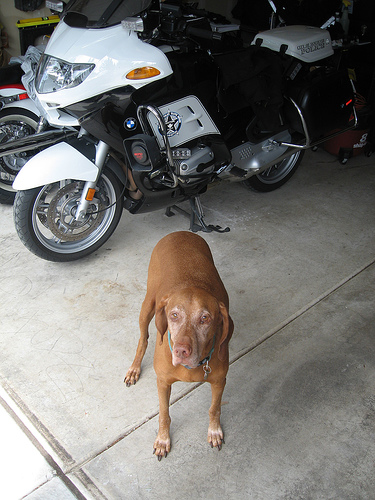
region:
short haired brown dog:
[118, 226, 273, 468]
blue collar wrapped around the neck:
[160, 330, 220, 377]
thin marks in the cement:
[30, 324, 104, 410]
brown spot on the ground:
[72, 271, 135, 322]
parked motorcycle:
[15, 12, 354, 263]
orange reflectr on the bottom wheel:
[84, 185, 98, 204]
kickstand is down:
[181, 193, 232, 233]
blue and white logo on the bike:
[121, 113, 139, 133]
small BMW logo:
[119, 116, 144, 133]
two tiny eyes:
[163, 307, 214, 324]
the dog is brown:
[133, 213, 294, 471]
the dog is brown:
[134, 328, 211, 477]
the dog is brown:
[181, 315, 242, 495]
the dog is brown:
[128, 225, 198, 458]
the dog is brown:
[141, 270, 235, 495]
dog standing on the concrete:
[96, 230, 276, 467]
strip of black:
[0, 399, 87, 498]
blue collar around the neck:
[164, 330, 226, 382]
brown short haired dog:
[101, 226, 271, 466]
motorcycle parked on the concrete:
[9, 12, 315, 260]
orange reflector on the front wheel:
[79, 187, 100, 199]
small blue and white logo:
[121, 112, 139, 132]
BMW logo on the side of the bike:
[119, 113, 138, 131]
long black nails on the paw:
[150, 447, 172, 463]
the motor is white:
[33, 20, 176, 181]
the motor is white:
[23, 41, 224, 295]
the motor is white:
[39, 19, 254, 485]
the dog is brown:
[121, 271, 222, 417]